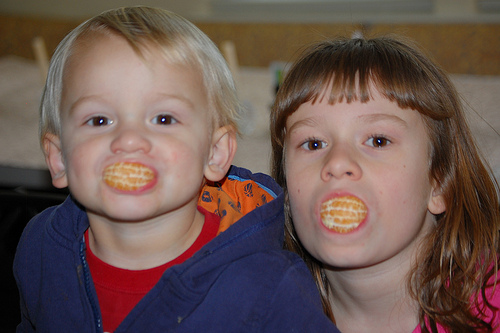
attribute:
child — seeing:
[13, 0, 333, 323]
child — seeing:
[270, 34, 499, 331]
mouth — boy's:
[103, 158, 163, 194]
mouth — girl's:
[308, 188, 372, 236]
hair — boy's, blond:
[36, 4, 241, 143]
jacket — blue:
[13, 167, 336, 326]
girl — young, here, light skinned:
[261, 26, 494, 332]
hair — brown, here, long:
[268, 28, 499, 325]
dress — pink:
[412, 252, 500, 329]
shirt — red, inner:
[78, 208, 221, 323]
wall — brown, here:
[7, 5, 497, 187]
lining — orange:
[203, 174, 272, 232]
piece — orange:
[105, 157, 156, 187]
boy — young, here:
[14, 1, 328, 324]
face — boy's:
[58, 36, 213, 223]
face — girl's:
[286, 98, 422, 262]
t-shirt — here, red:
[84, 211, 218, 324]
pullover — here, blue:
[10, 163, 338, 327]